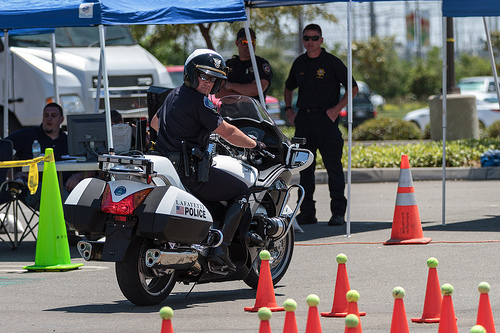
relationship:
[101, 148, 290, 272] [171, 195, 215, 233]
motorcycle with decal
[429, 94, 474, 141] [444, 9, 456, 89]
base of a pole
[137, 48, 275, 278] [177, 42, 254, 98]
officer wearing a helmet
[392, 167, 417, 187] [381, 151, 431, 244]
tape on cone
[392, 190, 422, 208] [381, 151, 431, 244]
tape on cone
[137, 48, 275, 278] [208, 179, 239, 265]
officer wearing boots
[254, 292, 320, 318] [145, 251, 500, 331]
balls on cones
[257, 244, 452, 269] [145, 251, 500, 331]
balls on cones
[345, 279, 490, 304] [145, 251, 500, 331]
balls on cones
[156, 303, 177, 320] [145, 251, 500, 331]
balls on cones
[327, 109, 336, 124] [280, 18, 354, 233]
hand of officer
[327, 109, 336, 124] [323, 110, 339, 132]
hand in pocket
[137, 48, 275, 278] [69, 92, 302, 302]
officer on motorcycle